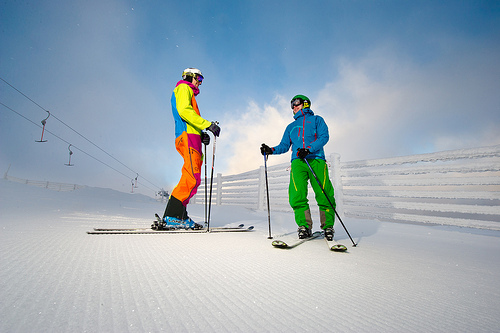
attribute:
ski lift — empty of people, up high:
[0, 76, 175, 211]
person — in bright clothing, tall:
[152, 64, 221, 229]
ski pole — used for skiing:
[195, 126, 213, 233]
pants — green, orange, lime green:
[284, 157, 336, 228]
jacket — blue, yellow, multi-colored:
[266, 108, 329, 161]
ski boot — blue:
[159, 213, 200, 229]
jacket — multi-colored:
[169, 81, 210, 134]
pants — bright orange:
[163, 132, 205, 229]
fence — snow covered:
[188, 150, 500, 232]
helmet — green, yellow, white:
[289, 94, 312, 108]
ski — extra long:
[84, 227, 254, 234]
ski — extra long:
[93, 222, 249, 231]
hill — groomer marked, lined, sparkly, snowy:
[1, 179, 499, 329]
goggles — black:
[182, 71, 203, 83]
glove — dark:
[207, 121, 221, 136]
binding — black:
[297, 224, 310, 240]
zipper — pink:
[299, 106, 308, 158]